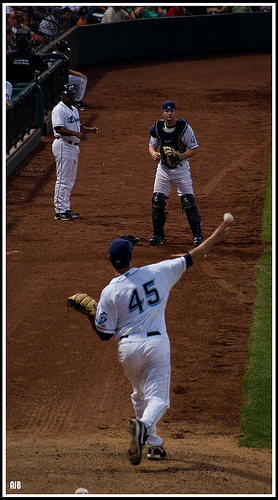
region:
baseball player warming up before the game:
[65, 212, 237, 462]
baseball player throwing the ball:
[65, 210, 234, 464]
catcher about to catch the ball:
[146, 101, 201, 248]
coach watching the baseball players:
[51, 82, 100, 221]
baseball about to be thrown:
[222, 211, 235, 224]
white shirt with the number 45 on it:
[96, 256, 186, 336]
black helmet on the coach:
[60, 83, 77, 98]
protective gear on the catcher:
[155, 118, 188, 168]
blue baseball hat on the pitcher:
[107, 238, 134, 261]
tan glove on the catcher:
[159, 145, 181, 167]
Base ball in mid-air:
[219, 210, 233, 224]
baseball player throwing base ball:
[68, 217, 236, 466]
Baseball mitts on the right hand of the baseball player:
[159, 145, 184, 168]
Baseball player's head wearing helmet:
[54, 81, 80, 107]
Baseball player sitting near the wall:
[41, 37, 90, 109]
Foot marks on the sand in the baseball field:
[204, 81, 272, 109]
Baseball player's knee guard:
[145, 192, 203, 248]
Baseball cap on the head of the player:
[105, 237, 133, 260]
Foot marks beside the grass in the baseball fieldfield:
[162, 154, 267, 440]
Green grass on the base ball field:
[238, 201, 270, 449]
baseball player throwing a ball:
[58, 209, 239, 463]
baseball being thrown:
[211, 211, 237, 248]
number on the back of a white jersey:
[123, 277, 162, 315]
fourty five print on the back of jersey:
[125, 276, 162, 315]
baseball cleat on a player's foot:
[125, 416, 148, 466]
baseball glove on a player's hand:
[63, 290, 98, 315]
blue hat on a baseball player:
[107, 236, 135, 265]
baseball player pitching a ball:
[61, 210, 236, 464]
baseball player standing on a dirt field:
[46, 81, 101, 222]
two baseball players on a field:
[50, 81, 208, 247]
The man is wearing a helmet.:
[44, 76, 99, 228]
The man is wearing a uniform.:
[44, 80, 101, 225]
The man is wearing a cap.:
[132, 92, 211, 251]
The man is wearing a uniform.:
[136, 97, 207, 258]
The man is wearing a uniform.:
[48, 206, 237, 471]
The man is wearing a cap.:
[56, 205, 239, 468]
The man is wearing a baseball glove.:
[139, 95, 211, 253]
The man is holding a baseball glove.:
[53, 208, 239, 467]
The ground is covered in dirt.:
[6, 50, 260, 498]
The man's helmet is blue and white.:
[36, 74, 101, 225]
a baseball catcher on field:
[147, 100, 203, 246]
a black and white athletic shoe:
[125, 417, 145, 465]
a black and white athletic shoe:
[147, 446, 166, 459]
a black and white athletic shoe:
[53, 212, 72, 221]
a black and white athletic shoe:
[67, 208, 77, 216]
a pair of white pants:
[117, 332, 170, 445]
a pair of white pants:
[51, 138, 79, 212]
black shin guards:
[151, 191, 166, 235]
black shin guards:
[179, 193, 202, 235]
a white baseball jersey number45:
[95, 258, 185, 335]